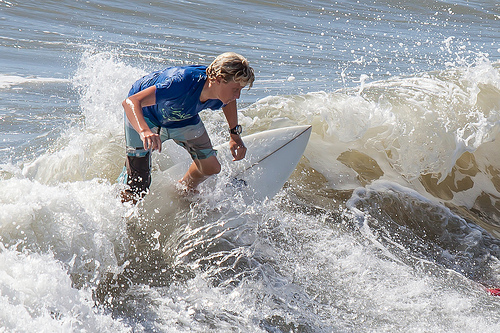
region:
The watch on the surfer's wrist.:
[232, 122, 244, 137]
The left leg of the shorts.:
[123, 125, 158, 189]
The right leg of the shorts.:
[185, 124, 220, 159]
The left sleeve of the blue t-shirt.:
[157, 73, 181, 98]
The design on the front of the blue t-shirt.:
[166, 101, 196, 126]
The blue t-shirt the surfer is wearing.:
[135, 57, 226, 134]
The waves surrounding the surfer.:
[44, 37, 499, 318]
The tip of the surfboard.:
[260, 116, 321, 155]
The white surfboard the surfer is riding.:
[94, 99, 325, 250]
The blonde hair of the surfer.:
[204, 41, 264, 89]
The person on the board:
[104, 39, 260, 206]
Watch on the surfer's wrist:
[225, 121, 243, 137]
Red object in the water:
[481, 282, 498, 301]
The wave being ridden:
[4, 38, 499, 332]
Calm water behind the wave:
[2, 1, 499, 161]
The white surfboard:
[162, 113, 316, 218]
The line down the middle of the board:
[232, 125, 309, 180]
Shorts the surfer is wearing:
[112, 114, 218, 191]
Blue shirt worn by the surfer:
[122, 57, 233, 125]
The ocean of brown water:
[0, 1, 499, 329]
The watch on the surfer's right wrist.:
[230, 122, 243, 137]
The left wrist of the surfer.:
[129, 124, 156, 141]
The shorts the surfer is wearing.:
[117, 122, 214, 190]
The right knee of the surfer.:
[203, 159, 225, 182]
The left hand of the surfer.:
[141, 130, 167, 152]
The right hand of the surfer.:
[228, 136, 253, 163]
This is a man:
[117, 49, 219, 303]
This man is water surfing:
[114, 48, 336, 264]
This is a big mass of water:
[1, 3, 493, 323]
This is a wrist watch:
[228, 124, 242, 136]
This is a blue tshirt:
[125, 59, 215, 124]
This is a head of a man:
[203, 48, 259, 122]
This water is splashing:
[1, 43, 496, 331]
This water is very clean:
[0, 59, 497, 331]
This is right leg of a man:
[123, 108, 161, 213]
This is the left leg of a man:
[167, 117, 225, 197]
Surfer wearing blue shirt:
[131, 57, 217, 149]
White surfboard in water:
[189, 116, 372, 226]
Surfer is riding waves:
[58, 67, 396, 310]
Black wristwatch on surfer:
[209, 112, 271, 169]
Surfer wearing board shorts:
[114, 100, 251, 173]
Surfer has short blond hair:
[201, 50, 276, 101]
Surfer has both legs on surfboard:
[65, 105, 270, 267]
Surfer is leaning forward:
[106, 32, 303, 212]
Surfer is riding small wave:
[146, 47, 482, 324]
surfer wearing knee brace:
[103, 133, 183, 238]